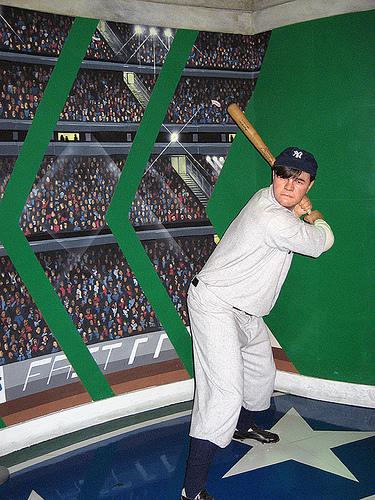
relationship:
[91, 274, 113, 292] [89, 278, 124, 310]
spectator in stands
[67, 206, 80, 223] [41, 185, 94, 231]
spectator on stands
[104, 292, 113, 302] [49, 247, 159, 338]
spectator on stands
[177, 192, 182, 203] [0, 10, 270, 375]
spectator sitting in stands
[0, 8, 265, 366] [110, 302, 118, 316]
spectator sitting in stands